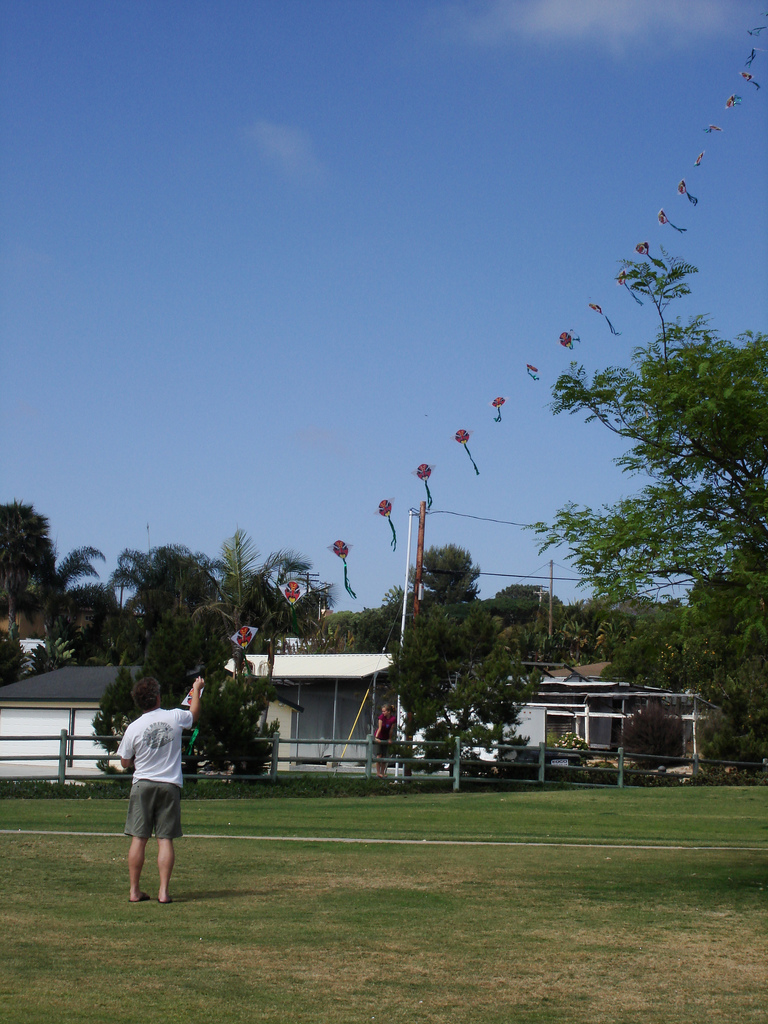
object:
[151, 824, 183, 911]
leg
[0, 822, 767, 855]
line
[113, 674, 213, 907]
man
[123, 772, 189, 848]
pants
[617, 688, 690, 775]
bush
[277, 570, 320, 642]
kite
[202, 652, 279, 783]
tree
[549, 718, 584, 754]
plant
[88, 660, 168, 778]
tree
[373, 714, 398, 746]
shirt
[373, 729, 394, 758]
shorts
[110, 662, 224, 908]
person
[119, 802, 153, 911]
leg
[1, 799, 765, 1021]
ground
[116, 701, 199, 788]
shirt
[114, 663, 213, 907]
man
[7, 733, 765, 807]
fence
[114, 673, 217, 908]
man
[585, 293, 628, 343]
kite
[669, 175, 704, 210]
kite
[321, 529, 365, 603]
kite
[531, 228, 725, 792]
tree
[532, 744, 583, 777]
table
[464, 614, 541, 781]
tree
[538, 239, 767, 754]
tree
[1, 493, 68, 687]
tree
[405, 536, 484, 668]
tree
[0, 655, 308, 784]
house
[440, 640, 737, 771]
house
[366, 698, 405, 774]
girl